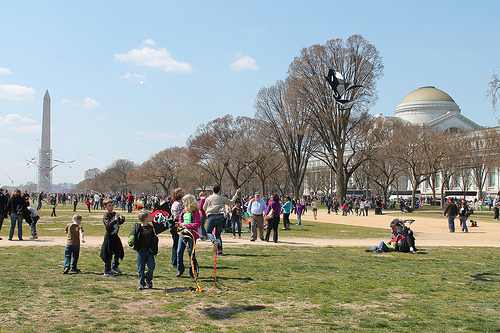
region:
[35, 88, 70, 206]
A BUILDING IN THE DISTANCE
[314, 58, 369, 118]
A BLACK AND WHITE KITE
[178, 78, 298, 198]
TREES IN THE BACKGROUND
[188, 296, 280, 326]
A SHADOW ON THE GRASS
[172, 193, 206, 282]
A GIRL WEARING A PINK SWEATER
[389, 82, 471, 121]
A DOME ON TOP OF A BUILDING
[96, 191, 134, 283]
A KID WITH HIS JACKET TIED AROUND HIS WASTE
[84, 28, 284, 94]
CLOUDS IN THE SKY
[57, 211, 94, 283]
A BOY WEARING BLUE JEANS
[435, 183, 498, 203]
A BUS OUTSIDE OF A BUILDING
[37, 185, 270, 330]
the children are playing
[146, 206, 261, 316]
the kite has a skull on it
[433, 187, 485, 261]
they are walking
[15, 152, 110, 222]
kites are in the sky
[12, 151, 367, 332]
they are in the park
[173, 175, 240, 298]
the girl has a pink jacket on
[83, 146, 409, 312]
the trees are brown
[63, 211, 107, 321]
he has a brown shirt on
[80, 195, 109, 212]
the child has red on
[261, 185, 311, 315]
she has a purple shirt on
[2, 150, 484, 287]
Several people are in the park.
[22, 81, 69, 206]
The Washington Monument is in the background.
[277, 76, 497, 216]
A museum building is in the background.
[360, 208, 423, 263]
A person is sitting on the ground.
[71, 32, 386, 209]
Trees are in the park.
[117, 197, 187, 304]
A child is pointing.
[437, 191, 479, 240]
A couple is walking.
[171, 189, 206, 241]
The woman wears a pink jacket.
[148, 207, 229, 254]
The woman is holding a toy.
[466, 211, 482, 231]
A dog is walking.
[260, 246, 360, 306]
the grass is green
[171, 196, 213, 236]
the jacket is pink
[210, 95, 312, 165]
the trees are brown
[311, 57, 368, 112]
the kite is flying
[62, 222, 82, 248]
the shirt is brown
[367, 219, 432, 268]
the people are sitting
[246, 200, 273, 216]
the shirt is blue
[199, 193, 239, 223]
the jacket is beige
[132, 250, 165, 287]
the jeans are blue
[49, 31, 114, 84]
the sky is blue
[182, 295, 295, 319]
large shadow on ground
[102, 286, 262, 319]
sparse green grass on ground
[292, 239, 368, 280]
cluster of green grass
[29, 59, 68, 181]
large oblong shape monument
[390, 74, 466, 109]
large gray dome building top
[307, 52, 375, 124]
black and white kite in tree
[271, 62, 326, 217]
tall thin trees without leaves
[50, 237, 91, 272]
boy wearing blue jean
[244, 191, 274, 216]
man with red bag on his shoulders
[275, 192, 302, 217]
man wearing green shirt